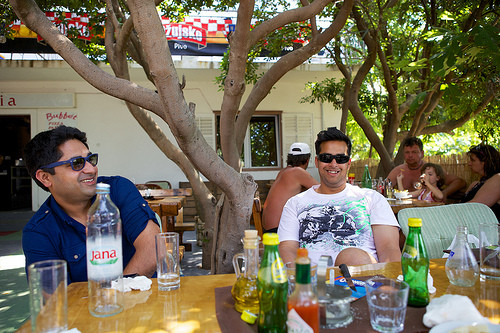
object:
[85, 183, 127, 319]
bottle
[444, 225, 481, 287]
bottles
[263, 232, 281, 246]
caps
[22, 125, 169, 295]
man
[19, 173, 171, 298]
shirt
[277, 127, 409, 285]
man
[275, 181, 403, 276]
shirt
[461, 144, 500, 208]
woman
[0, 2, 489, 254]
background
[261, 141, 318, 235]
man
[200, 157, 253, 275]
trunk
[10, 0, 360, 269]
tree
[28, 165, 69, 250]
glass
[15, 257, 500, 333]
table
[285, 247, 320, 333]
bottle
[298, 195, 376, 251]
design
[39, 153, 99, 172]
sunglasses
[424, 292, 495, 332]
napkin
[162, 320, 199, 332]
sun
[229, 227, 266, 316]
bottle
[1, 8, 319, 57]
sign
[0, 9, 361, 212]
building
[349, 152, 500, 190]
fence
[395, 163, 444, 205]
child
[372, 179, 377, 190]
glass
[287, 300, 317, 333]
hot suace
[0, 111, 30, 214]
entryway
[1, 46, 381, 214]
restaurant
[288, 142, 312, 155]
cap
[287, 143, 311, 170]
head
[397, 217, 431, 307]
bottle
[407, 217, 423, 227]
cap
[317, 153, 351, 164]
sunglasses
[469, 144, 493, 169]
sunglasses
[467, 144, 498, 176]
head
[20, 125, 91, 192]
hair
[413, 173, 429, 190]
can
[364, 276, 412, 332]
tumbler